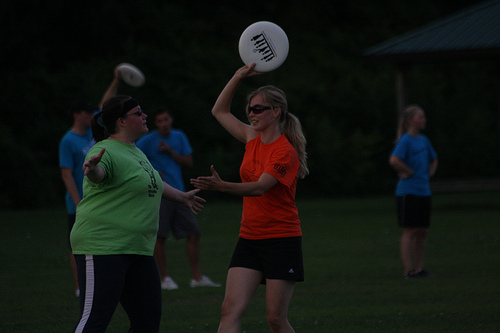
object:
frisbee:
[114, 60, 149, 89]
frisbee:
[235, 18, 293, 76]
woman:
[190, 58, 317, 332]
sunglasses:
[243, 102, 280, 113]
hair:
[246, 80, 313, 182]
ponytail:
[282, 106, 313, 186]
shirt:
[232, 128, 306, 245]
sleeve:
[261, 143, 299, 187]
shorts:
[223, 229, 311, 288]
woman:
[66, 91, 173, 333]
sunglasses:
[121, 104, 145, 123]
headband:
[100, 94, 141, 119]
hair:
[84, 91, 138, 149]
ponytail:
[86, 108, 109, 148]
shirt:
[65, 132, 165, 255]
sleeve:
[79, 143, 116, 186]